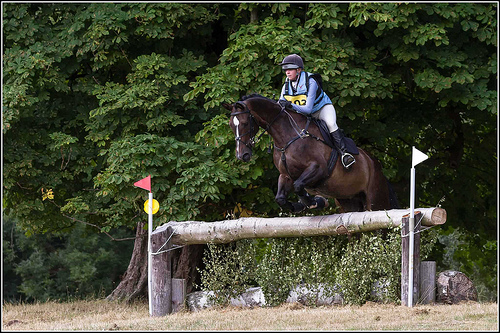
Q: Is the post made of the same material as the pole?
A: Yes, both the post and the pole are made of metal.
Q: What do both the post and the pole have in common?
A: The material, both the post and the pole are metallic.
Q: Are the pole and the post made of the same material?
A: Yes, both the pole and the post are made of metal.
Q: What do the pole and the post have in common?
A: The material, both the pole and the post are metallic.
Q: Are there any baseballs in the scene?
A: No, there are no baseballs.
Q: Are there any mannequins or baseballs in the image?
A: No, there are no baseballs or mannequins.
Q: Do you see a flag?
A: Yes, there is a flag.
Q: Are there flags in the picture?
A: Yes, there is a flag.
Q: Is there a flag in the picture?
A: Yes, there is a flag.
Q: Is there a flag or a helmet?
A: Yes, there is a flag.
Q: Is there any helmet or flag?
A: Yes, there is a flag.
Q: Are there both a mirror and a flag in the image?
A: No, there is a flag but no mirrors.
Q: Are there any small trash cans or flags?
A: Yes, there is a small flag.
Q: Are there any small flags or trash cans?
A: Yes, there is a small flag.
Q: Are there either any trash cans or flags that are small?
A: Yes, the flag is small.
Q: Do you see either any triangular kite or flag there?
A: Yes, there is a triangular flag.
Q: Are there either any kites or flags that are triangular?
A: Yes, the flag is triangular.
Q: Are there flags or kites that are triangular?
A: Yes, the flag is triangular.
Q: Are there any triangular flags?
A: Yes, there is a triangular flag.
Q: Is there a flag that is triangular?
A: Yes, there is a flag that is triangular.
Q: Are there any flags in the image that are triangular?
A: Yes, there is a flag that is triangular.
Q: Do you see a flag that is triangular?
A: Yes, there is a flag that is triangular.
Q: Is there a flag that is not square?
A: Yes, there is a triangular flag.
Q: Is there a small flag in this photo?
A: Yes, there is a small flag.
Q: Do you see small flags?
A: Yes, there is a small flag.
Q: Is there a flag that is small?
A: Yes, there is a flag that is small.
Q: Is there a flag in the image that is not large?
A: Yes, there is a small flag.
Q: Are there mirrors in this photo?
A: No, there are no mirrors.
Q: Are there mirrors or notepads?
A: No, there are no mirrors or notepads.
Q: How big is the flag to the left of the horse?
A: The flag is small.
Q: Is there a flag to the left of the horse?
A: Yes, there is a flag to the left of the horse.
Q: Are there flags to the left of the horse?
A: Yes, there is a flag to the left of the horse.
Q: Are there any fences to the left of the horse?
A: No, there is a flag to the left of the horse.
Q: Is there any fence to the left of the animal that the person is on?
A: No, there is a flag to the left of the horse.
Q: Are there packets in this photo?
A: No, there are no packets.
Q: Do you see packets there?
A: No, there are no packets.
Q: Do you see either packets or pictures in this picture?
A: No, there are no packets or pictures.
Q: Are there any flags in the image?
A: Yes, there is a flag.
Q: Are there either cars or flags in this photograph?
A: Yes, there is a flag.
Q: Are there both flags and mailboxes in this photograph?
A: No, there is a flag but no mailboxes.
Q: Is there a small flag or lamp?
A: Yes, there is a small flag.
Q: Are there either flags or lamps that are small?
A: Yes, the flag is small.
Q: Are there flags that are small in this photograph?
A: Yes, there is a small flag.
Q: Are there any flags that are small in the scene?
A: Yes, there is a small flag.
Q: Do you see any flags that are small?
A: Yes, there is a flag that is small.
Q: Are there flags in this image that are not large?
A: Yes, there is a small flag.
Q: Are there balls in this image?
A: No, there are no balls.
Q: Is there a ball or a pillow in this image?
A: No, there are no balls or pillows.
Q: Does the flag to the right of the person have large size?
A: No, the flag is small.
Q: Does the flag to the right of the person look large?
A: No, the flag is small.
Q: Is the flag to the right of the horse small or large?
A: The flag is small.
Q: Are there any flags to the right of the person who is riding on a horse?
A: Yes, there is a flag to the right of the person.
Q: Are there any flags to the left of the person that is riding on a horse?
A: No, the flag is to the right of the person.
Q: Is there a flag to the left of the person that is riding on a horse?
A: No, the flag is to the right of the person.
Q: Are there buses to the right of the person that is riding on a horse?
A: No, there is a flag to the right of the person.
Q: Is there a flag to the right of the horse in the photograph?
A: Yes, there is a flag to the right of the horse.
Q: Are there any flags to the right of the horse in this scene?
A: Yes, there is a flag to the right of the horse.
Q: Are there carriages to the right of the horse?
A: No, there is a flag to the right of the horse.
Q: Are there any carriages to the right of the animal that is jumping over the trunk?
A: No, there is a flag to the right of the horse.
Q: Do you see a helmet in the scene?
A: Yes, there is a helmet.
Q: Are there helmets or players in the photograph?
A: Yes, there is a helmet.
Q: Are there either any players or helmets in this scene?
A: Yes, there is a helmet.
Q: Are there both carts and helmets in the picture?
A: No, there is a helmet but no carts.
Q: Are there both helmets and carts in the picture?
A: No, there is a helmet but no carts.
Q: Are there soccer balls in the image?
A: No, there are no soccer balls.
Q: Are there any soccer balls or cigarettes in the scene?
A: No, there are no soccer balls or cigarettes.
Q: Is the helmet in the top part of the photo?
A: Yes, the helmet is in the top of the image.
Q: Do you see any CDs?
A: No, there are no cds.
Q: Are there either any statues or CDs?
A: No, there are no CDs or statues.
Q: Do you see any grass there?
A: Yes, there is grass.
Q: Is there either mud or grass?
A: Yes, there is grass.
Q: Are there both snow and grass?
A: No, there is grass but no snow.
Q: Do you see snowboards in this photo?
A: No, there are no snowboards.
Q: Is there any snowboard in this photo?
A: No, there are no snowboards.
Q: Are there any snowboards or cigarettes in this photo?
A: No, there are no snowboards or cigarettes.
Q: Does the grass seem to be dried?
A: Yes, the grass is dried.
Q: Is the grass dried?
A: Yes, the grass is dried.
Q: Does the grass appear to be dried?
A: Yes, the grass is dried.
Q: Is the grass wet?
A: No, the grass is dried.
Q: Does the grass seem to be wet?
A: No, the grass is dried.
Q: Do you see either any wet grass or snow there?
A: No, there is grass but it is dried.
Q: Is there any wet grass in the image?
A: No, there is grass but it is dried.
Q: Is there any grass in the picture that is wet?
A: No, there is grass but it is dried.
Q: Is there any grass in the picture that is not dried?
A: No, there is grass but it is dried.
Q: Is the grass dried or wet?
A: The grass is dried.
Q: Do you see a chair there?
A: No, there are no chairs.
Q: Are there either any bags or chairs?
A: No, there are no chairs or bags.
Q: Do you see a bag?
A: No, there are no bags.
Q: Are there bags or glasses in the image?
A: No, there are no bags or glasses.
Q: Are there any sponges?
A: No, there are no sponges.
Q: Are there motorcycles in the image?
A: No, there are no motorcycles.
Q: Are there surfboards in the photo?
A: No, there are no surfboards.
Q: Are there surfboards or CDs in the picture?
A: No, there are no surfboards or cds.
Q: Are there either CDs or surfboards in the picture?
A: No, there are no surfboards or cds.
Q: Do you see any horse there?
A: Yes, there is a horse.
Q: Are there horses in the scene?
A: Yes, there is a horse.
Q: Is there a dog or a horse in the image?
A: Yes, there is a horse.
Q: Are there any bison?
A: No, there are no bison.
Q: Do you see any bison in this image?
A: No, there are no bison.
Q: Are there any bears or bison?
A: No, there are no bison or bears.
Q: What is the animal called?
A: The animal is a horse.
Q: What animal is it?
A: The animal is a horse.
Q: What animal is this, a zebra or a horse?
A: This is a horse.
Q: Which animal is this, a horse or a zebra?
A: This is a horse.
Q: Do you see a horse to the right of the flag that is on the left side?
A: Yes, there is a horse to the right of the flag.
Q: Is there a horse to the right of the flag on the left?
A: Yes, there is a horse to the right of the flag.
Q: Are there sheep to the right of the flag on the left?
A: No, there is a horse to the right of the flag.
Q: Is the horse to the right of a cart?
A: No, the horse is to the right of the flag.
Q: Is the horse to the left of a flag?
A: No, the horse is to the right of a flag.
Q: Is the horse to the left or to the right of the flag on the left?
A: The horse is to the right of the flag.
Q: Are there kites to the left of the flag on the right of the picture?
A: No, there is a horse to the left of the flag.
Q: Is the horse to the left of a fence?
A: No, the horse is to the left of a flag.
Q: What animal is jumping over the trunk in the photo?
A: The horse is jumping over the trunk.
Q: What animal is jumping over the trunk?
A: The horse is jumping over the trunk.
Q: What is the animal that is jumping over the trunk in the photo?
A: The animal is a horse.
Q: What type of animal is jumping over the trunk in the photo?
A: The animal is a horse.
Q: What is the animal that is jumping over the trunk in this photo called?
A: The animal is a horse.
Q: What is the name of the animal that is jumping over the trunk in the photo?
A: The animal is a horse.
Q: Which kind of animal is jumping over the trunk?
A: The animal is a horse.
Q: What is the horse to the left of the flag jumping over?
A: The horse is jumping over the trunk.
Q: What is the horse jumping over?
A: The horse is jumping over the trunk.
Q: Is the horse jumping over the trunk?
A: Yes, the horse is jumping over the trunk.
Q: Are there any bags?
A: No, there are no bags.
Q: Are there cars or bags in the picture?
A: No, there are no bags or cars.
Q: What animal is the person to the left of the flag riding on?
A: The person is riding on a horse.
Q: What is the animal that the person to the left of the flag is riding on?
A: The animal is a horse.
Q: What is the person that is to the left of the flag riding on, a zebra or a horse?
A: The person is riding on a horse.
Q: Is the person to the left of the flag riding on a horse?
A: Yes, the person is riding on a horse.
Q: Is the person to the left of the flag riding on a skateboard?
A: No, the person is riding on a horse.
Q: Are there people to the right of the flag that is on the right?
A: No, the person is to the left of the flag.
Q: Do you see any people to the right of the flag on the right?
A: No, the person is to the left of the flag.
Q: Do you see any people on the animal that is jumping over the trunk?
A: Yes, there is a person on the horse.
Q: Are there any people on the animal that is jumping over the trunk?
A: Yes, there is a person on the horse.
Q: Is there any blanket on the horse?
A: No, there is a person on the horse.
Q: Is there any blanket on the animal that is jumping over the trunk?
A: No, there is a person on the horse.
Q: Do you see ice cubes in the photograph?
A: No, there are no ice cubes.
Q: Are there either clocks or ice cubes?
A: No, there are no ice cubes or clocks.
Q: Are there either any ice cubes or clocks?
A: No, there are no ice cubes or clocks.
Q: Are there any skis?
A: No, there are no skis.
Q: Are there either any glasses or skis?
A: No, there are no skis or glasses.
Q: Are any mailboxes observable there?
A: No, there are no mailboxes.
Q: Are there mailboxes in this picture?
A: No, there are no mailboxes.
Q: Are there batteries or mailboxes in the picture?
A: No, there are no mailboxes or batteries.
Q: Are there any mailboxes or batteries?
A: No, there are no mailboxes or batteries.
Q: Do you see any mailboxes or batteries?
A: No, there are no mailboxes or batteries.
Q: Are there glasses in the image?
A: No, there are no glasses.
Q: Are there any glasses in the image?
A: No, there are no glasses.